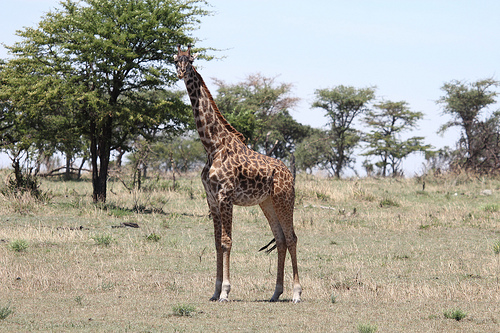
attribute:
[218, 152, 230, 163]
spot — brown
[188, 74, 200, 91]
spot — brown 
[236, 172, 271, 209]
belly — bulky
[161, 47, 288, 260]
giraffe — adult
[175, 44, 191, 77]
head — small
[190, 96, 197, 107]
spot — brown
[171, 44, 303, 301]
giraffe — big, adult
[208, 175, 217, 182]
spot — brown 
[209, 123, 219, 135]
spot — brown 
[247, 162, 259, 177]
spot — brown 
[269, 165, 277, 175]
spot — brown 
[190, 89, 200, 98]
spot — brown 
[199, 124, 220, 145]
spot — brown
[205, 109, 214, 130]
spot — brown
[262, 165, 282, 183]
spot — brown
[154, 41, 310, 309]
giraffe — adult, grown